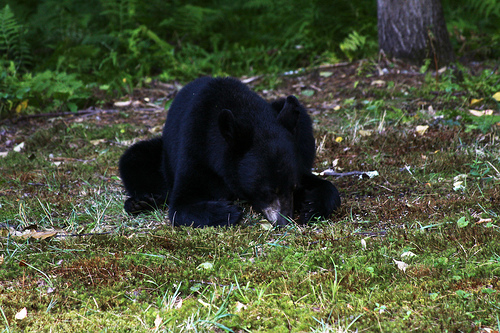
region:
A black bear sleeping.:
[116, 77, 346, 226]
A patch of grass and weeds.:
[0, 230, 499, 330]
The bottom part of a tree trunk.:
[371, 4, 445, 61]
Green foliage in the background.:
[0, 0, 229, 72]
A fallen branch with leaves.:
[2, 223, 116, 240]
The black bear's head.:
[239, 132, 296, 223]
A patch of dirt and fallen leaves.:
[289, 65, 379, 105]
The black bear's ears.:
[207, 94, 304, 129]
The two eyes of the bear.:
[248, 182, 307, 195]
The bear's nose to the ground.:
[262, 202, 284, 226]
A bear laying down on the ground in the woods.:
[110, 69, 354, 234]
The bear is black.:
[115, 74, 355, 245]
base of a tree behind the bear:
[370, 0, 466, 75]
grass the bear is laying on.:
[125, 220, 361, 261]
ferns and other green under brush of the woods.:
[0, 14, 382, 69]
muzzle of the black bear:
[259, 196, 296, 226]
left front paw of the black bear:
[172, 189, 252, 241]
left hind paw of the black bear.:
[107, 180, 168, 217]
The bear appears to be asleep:
[116, 77, 343, 232]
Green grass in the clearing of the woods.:
[197, 242, 365, 309]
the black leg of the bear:
[115, 138, 169, 214]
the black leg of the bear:
[270, 93, 322, 171]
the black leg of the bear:
[166, 142, 237, 227]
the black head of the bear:
[242, 143, 297, 225]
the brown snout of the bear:
[263, 199, 293, 224]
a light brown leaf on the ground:
[13, 226, 55, 241]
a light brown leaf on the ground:
[413, 122, 428, 134]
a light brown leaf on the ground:
[85, 136, 107, 145]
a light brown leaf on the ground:
[112, 96, 130, 111]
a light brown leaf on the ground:
[452, 180, 464, 191]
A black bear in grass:
[107, 66, 347, 238]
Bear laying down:
[108, 75, 348, 225]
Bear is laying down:
[115, 65, 350, 232]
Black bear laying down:
[105, 68, 355, 235]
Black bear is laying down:
[108, 68, 348, 230]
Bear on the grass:
[110, 69, 351, 229]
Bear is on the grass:
[113, 70, 345, 236]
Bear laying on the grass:
[114, 70, 350, 239]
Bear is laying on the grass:
[113, 71, 347, 228]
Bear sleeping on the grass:
[112, 69, 350, 234]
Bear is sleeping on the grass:
[110, 70, 347, 237]